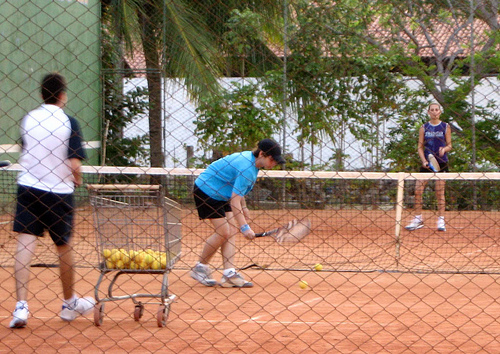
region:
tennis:
[22, 33, 491, 328]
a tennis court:
[16, 14, 496, 346]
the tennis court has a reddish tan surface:
[19, 186, 498, 351]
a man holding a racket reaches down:
[196, 128, 328, 308]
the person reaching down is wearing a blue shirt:
[191, 123, 323, 293]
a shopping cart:
[86, 176, 188, 332]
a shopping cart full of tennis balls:
[86, 175, 196, 333]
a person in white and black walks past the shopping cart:
[14, 56, 188, 329]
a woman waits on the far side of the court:
[414, 98, 459, 240]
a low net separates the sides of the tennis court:
[46, 161, 498, 272]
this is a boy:
[188, 131, 278, 286]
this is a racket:
[258, 219, 313, 245]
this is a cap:
[263, 138, 285, 158]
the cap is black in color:
[264, 139, 279, 148]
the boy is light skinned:
[261, 159, 271, 162]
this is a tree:
[291, 12, 398, 127]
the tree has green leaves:
[313, 50, 340, 88]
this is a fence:
[282, 7, 417, 229]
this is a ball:
[314, 261, 323, 268]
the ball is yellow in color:
[313, 261, 324, 269]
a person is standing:
[8, 62, 105, 333]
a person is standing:
[398, 95, 458, 237]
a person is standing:
[195, 133, 308, 306]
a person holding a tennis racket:
[180, 127, 317, 298]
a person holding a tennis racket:
[391, 93, 456, 238]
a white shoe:
[52, 287, 94, 326]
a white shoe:
[8, 305, 29, 328]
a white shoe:
[221, 267, 253, 292]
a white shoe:
[190, 262, 219, 287]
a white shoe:
[436, 216, 447, 236]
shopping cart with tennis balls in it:
[77, 177, 191, 329]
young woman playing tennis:
[401, 95, 465, 242]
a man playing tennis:
[179, 120, 334, 292]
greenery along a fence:
[169, 26, 416, 133]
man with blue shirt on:
[182, 115, 297, 226]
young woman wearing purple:
[401, 95, 478, 169]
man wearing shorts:
[8, 60, 93, 345]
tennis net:
[314, 157, 416, 286]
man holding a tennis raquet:
[186, 130, 323, 254]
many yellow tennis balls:
[98, 245, 170, 271]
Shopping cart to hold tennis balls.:
[83, 173, 199, 330]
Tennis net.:
[79, 157, 498, 284]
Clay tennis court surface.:
[317, 205, 492, 351]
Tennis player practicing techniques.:
[396, 95, 458, 239]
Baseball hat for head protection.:
[249, 117, 291, 178]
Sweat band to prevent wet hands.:
[233, 212, 267, 249]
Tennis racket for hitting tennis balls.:
[411, 142, 461, 179]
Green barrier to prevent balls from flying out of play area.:
[0, 6, 102, 208]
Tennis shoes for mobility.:
[402, 205, 453, 235]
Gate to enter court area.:
[92, 50, 177, 215]